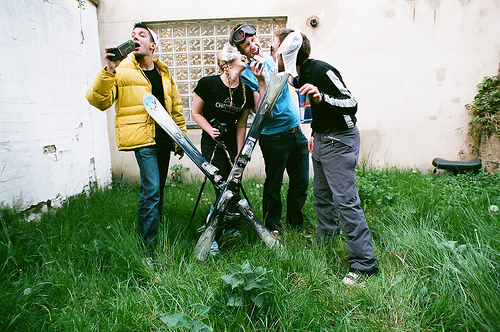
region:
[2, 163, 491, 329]
tall green grass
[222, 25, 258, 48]
black goggles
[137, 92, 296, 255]
a long ski pole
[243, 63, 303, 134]
a man's blue shirt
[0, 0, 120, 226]
part of a white wall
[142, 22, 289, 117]
part of a glass window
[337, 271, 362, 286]
part of a man's tennis shoe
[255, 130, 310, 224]
a man's black pants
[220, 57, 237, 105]
a girl's long braided hair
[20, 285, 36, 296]
a small white flower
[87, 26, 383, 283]
people standing behind crossed ski poles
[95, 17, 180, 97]
man lifting bottle to open mouth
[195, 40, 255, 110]
woman in braids with head to side laughing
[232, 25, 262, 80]
man with goggles lifting object to mouth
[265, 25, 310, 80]
man with white brassiere over head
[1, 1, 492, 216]
white brick wall next to flat wall with window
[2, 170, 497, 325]
overgrown yard with tall grasses and weeds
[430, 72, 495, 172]
low black seat next to planter with greenery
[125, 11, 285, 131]
glass-block tiles set into large window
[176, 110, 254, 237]
woman holding black ski poles behind skis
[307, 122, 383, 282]
man wearing gray pants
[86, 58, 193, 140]
man wearing a yellow jacket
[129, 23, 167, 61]
man wearing a white hat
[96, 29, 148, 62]
man drinking from a bottle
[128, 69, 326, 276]
skis in front of a group of people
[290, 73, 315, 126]
man holding a red bull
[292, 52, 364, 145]
man wearing a black sweater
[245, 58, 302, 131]
man wearing a blue tee shirt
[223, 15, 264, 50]
man wearing ski googles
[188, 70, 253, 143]
woman wearing a black tee shirt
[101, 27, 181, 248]
man wearing a jacket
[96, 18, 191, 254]
man wearing black shirt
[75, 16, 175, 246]
man wearing blue jeans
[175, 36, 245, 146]
woman wearing a black shirt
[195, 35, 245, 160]
woman wearing blue jeans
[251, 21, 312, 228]
man wearing blue shirt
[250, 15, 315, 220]
man wearing blue jeans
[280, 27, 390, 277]
man wearing black shirt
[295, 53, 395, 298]
man standing in grass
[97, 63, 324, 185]
a man is wearing a yellow jacket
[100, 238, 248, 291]
the grass is green under their feet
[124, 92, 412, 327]
two skis are in an x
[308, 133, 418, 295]
the man is wearing gray pants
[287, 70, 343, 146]
the man is holding a red bull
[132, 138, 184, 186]
the man is wearing jeans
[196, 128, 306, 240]
the woman is wearing black pants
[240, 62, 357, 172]
the man is wearing a blue shirt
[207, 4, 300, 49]
the man is wearing ski goggles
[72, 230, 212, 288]
the grass is overgrown